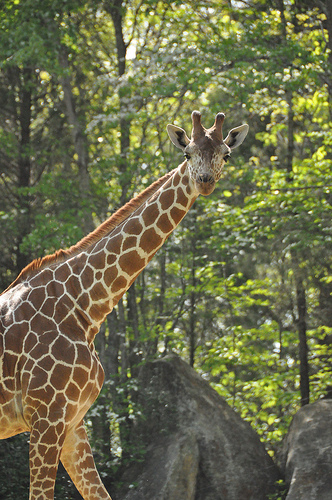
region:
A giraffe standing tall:
[0, 110, 247, 499]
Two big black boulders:
[112, 354, 330, 498]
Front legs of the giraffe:
[28, 416, 111, 499]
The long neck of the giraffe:
[40, 154, 197, 322]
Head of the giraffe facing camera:
[166, 110, 248, 195]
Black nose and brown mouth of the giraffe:
[195, 173, 213, 194]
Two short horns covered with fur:
[190, 109, 224, 141]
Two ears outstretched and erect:
[166, 123, 249, 149]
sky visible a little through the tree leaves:
[122, 0, 247, 59]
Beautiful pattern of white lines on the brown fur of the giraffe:
[0, 234, 106, 409]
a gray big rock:
[122, 348, 256, 492]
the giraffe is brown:
[34, 177, 163, 315]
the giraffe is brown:
[55, 197, 204, 357]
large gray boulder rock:
[99, 347, 278, 498]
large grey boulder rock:
[266, 399, 330, 495]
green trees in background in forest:
[4, 1, 331, 475]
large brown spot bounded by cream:
[48, 332, 80, 367]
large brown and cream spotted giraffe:
[2, 107, 251, 495]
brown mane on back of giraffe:
[7, 169, 176, 291]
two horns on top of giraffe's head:
[186, 108, 227, 143]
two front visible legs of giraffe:
[28, 420, 120, 497]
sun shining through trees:
[110, 0, 324, 497]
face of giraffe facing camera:
[168, 107, 251, 197]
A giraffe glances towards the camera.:
[162, 108, 253, 197]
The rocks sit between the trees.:
[112, 352, 279, 499]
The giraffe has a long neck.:
[65, 171, 200, 308]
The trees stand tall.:
[256, 108, 323, 379]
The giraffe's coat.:
[22, 304, 94, 391]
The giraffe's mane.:
[4, 173, 182, 253]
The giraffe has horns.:
[190, 108, 225, 132]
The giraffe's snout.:
[190, 172, 219, 197]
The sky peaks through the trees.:
[210, 289, 233, 305]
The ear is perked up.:
[164, 119, 192, 150]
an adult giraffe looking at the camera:
[17, 72, 271, 472]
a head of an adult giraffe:
[160, 114, 243, 195]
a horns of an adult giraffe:
[175, 99, 227, 134]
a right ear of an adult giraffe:
[161, 118, 196, 155]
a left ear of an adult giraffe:
[218, 119, 255, 155]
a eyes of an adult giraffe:
[176, 143, 237, 167]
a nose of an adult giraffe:
[197, 175, 217, 191]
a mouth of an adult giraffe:
[192, 171, 218, 197]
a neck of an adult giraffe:
[66, 172, 186, 313]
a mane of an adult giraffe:
[90, 219, 116, 242]